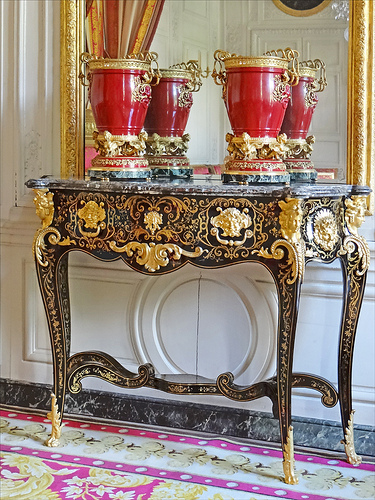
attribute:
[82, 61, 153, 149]
vase — red, gold, yellow, pretty, decorated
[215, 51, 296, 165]
vase — red, gold, yellow, decorated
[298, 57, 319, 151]
vase — red, gold, yellow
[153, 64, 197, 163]
vase — red, gold, yellow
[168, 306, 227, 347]
wall — white, circle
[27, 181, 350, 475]
table — black, gold, marble, yellow, ornate, pretty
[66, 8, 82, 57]
mirror — gold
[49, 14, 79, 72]
frame — gold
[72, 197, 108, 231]
sculpture — gold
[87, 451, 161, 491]
rug — pink, white, yellow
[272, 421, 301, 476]
leg — gold